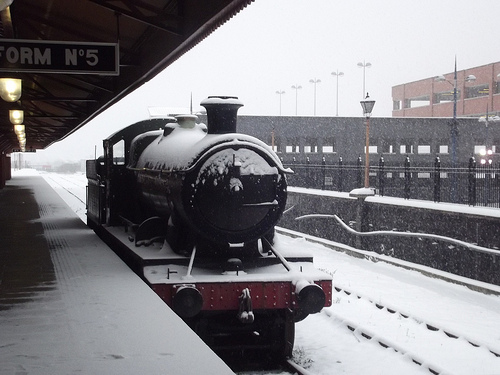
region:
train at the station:
[101, 109, 321, 336]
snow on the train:
[111, 107, 204, 164]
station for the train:
[73, 259, 148, 363]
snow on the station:
[42, 225, 179, 360]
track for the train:
[365, 283, 452, 368]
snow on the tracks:
[344, 277, 473, 364]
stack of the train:
[192, 88, 249, 133]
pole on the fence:
[340, 85, 397, 188]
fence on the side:
[342, 206, 492, 283]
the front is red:
[193, 266, 288, 296]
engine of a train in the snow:
[85, 107, 322, 372]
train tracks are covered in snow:
[20, 167, 493, 372]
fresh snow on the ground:
[0, 164, 495, 372]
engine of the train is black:
[86, 124, 307, 344]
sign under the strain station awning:
[0, 26, 117, 77]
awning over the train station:
[4, 7, 266, 174]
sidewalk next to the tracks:
[2, 174, 236, 370]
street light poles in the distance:
[269, 56, 372, 103]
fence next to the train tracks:
[280, 178, 497, 275]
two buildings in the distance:
[230, 49, 495, 289]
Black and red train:
[86, 90, 333, 372]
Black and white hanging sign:
[0, 39, 121, 81]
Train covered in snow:
[83, 91, 334, 368]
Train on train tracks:
[80, 93, 335, 367]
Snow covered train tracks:
[51, 167, 498, 374]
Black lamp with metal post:
[358, 88, 378, 191]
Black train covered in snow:
[81, 90, 332, 372]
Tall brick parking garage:
[388, 58, 498, 119]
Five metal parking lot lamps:
[270, 57, 375, 116]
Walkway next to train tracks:
[1, 163, 238, 373]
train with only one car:
[63, 88, 371, 369]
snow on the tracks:
[199, 213, 498, 373]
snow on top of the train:
[141, 93, 293, 187]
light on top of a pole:
[351, 90, 380, 182]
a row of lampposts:
[253, 56, 397, 126]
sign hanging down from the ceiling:
[1, 35, 123, 82]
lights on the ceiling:
[0, 72, 33, 157]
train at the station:
[1, 0, 346, 374]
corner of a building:
[381, 76, 401, 116]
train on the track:
[77, 102, 335, 333]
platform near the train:
[10, 275, 140, 355]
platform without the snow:
[6, 212, 37, 262]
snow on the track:
[352, 265, 397, 372]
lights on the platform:
[1, 77, 27, 158]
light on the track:
[352, 85, 372, 181]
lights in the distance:
[268, 80, 348, 97]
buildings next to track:
[263, 71, 499, 160]